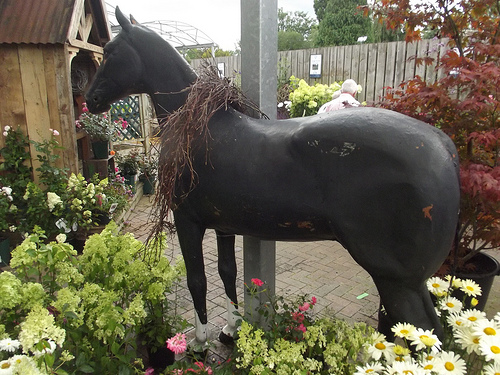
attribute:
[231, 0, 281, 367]
pole — silver, square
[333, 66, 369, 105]
hair — white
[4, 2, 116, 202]
shed — wooden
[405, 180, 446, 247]
paint chip — black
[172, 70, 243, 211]
vines — brown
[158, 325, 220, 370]
flowers — red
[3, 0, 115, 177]
shed — wood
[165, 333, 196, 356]
pink flower — larger , lighter 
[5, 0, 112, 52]
roof — rusted, tin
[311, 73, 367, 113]
man — white-haired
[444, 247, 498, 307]
pot — black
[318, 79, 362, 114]
man — older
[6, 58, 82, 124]
shed — wooden